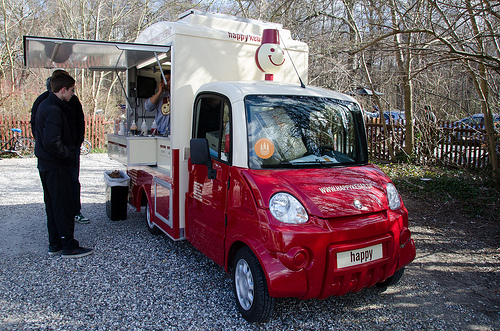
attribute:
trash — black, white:
[102, 169, 131, 222]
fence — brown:
[365, 126, 482, 178]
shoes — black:
[44, 242, 95, 259]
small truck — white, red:
[112, 17, 418, 292]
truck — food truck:
[116, 9, 412, 314]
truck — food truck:
[141, 11, 441, 317]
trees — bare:
[330, 2, 498, 92]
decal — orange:
[251, 134, 288, 165]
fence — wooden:
[364, 114, 499, 171]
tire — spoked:
[227, 243, 272, 325]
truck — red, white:
[25, 7, 415, 321]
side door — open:
[21, 33, 171, 85]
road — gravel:
[1, 151, 499, 330]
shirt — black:
[32, 94, 75, 168]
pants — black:
[37, 156, 80, 249]